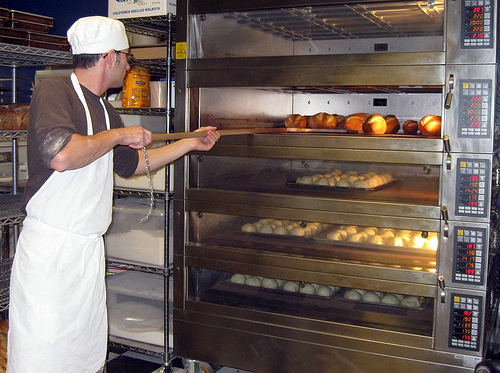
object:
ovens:
[160, 147, 493, 224]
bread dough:
[350, 178, 372, 191]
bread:
[360, 113, 389, 137]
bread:
[412, 114, 444, 137]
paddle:
[141, 126, 356, 144]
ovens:
[170, 0, 499, 72]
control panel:
[457, 79, 489, 138]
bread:
[280, 114, 308, 129]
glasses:
[100, 47, 134, 61]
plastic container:
[102, 267, 171, 348]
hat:
[65, 14, 130, 56]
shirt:
[18, 73, 140, 224]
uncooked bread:
[324, 174, 337, 185]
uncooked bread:
[310, 176, 328, 186]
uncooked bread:
[296, 176, 313, 185]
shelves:
[181, 168, 442, 221]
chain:
[135, 142, 155, 221]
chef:
[3, 15, 221, 373]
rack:
[195, 128, 440, 151]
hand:
[116, 124, 157, 149]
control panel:
[444, 291, 483, 352]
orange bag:
[120, 67, 151, 109]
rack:
[103, 105, 174, 117]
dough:
[333, 177, 353, 189]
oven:
[167, 200, 492, 293]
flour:
[100, 229, 174, 270]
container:
[101, 187, 177, 277]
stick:
[150, 126, 286, 141]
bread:
[340, 112, 366, 133]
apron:
[0, 72, 116, 372]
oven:
[173, 255, 485, 371]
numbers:
[470, 32, 478, 40]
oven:
[196, 64, 500, 156]